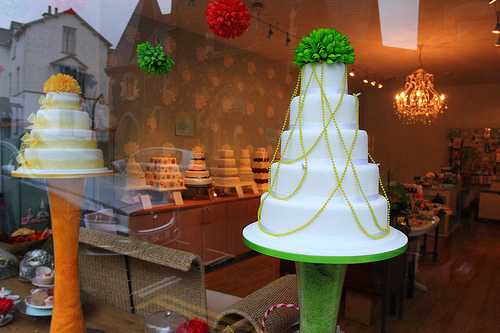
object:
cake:
[244, 21, 411, 246]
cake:
[19, 73, 109, 178]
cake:
[146, 150, 186, 196]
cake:
[121, 153, 148, 196]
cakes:
[145, 144, 188, 204]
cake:
[16, 90, 102, 169]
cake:
[255, 146, 274, 193]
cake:
[239, 144, 261, 190]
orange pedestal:
[43, 175, 85, 332]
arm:
[219, 278, 303, 328]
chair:
[37, 202, 343, 331]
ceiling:
[142, 0, 499, 87]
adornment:
[130, 41, 182, 73]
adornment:
[293, 26, 357, 63]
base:
[43, 180, 103, 329]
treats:
[400, 179, 446, 236]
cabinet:
[114, 196, 283, 279]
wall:
[117, 19, 330, 242]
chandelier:
[392, 41, 450, 125]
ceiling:
[353, 5, 484, 85]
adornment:
[40, 72, 82, 94]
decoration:
[205, 0, 252, 39]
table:
[409, 218, 441, 293]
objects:
[384, 174, 452, 226]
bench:
[99, 224, 262, 325]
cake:
[212, 146, 239, 187]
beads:
[263, 66, 392, 243]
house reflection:
[0, 7, 114, 99]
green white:
[241, 220, 408, 331]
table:
[241, 221, 410, 331]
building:
[14, 14, 114, 256]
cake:
[9, 70, 115, 179]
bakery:
[1, 2, 498, 332]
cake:
[188, 140, 208, 199]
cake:
[210, 139, 241, 192]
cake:
[249, 141, 263, 171]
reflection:
[0, 0, 499, 330]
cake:
[254, 64, 391, 245]